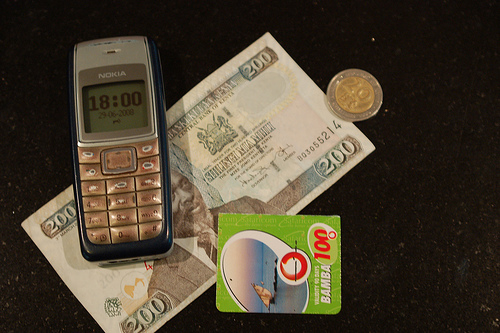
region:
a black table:
[2, 0, 482, 330]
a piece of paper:
[18, 30, 375, 332]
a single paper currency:
[17, 24, 379, 331]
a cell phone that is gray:
[60, 25, 190, 275]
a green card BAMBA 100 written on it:
[206, 190, 354, 331]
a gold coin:
[324, 55, 386, 132]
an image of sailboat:
[245, 278, 279, 309]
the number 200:
[304, 132, 361, 179]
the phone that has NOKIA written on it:
[86, 59, 135, 84]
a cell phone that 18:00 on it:
[82, 87, 151, 116]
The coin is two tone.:
[320, 62, 408, 144]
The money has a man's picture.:
[137, 152, 225, 324]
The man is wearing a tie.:
[151, 191, 236, 284]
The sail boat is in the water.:
[239, 272, 288, 312]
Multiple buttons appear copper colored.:
[65, 132, 167, 256]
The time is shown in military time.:
[68, 47, 168, 177]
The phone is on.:
[59, 40, 201, 262]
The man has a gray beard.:
[142, 167, 219, 264]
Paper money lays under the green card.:
[217, 47, 312, 285]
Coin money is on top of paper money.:
[305, 44, 395, 157]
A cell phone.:
[50, 22, 192, 271]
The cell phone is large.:
[51, 27, 183, 267]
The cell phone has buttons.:
[56, 19, 194, 279]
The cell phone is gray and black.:
[51, 23, 188, 261]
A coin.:
[316, 55, 393, 145]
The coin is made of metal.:
[320, 60, 398, 130]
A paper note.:
[16, 26, 376, 326]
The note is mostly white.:
[13, 27, 379, 327]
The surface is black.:
[393, 169, 490, 324]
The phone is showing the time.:
[59, 19, 200, 273]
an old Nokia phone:
[66, 31, 177, 263]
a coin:
[325, 64, 385, 122]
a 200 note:
[16, 31, 380, 332]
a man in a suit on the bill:
[145, 170, 290, 314]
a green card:
[216, 211, 343, 316]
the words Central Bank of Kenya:
[175, 86, 234, 142]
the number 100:
[312, 225, 333, 262]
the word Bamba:
[319, 263, 332, 304]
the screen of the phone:
[81, 77, 148, 134]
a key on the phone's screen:
[108, 115, 123, 127]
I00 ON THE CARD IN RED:
[308, 230, 334, 260]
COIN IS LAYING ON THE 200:
[326, 66, 376, 116]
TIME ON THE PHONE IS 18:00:
[85, 88, 147, 110]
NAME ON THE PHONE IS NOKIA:
[98, 64, 133, 81]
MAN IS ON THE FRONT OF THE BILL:
[170, 176, 207, 218]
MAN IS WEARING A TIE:
[203, 232, 218, 264]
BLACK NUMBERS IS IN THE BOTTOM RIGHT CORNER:
[283, 122, 347, 163]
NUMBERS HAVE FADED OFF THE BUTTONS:
[86, 183, 106, 193]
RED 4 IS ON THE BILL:
[141, 258, 158, 275]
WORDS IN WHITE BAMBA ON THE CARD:
[312, 258, 333, 305]